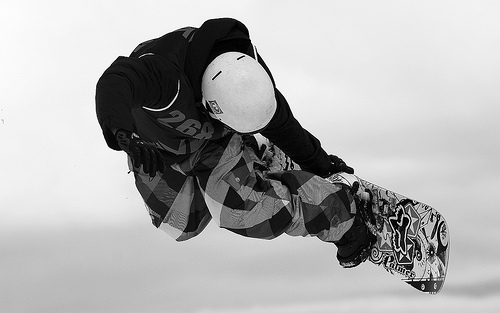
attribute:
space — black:
[209, 70, 223, 80]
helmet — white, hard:
[201, 50, 278, 135]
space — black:
[237, 53, 247, 61]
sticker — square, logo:
[207, 99, 223, 116]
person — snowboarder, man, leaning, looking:
[96, 17, 377, 269]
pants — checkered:
[128, 133, 357, 244]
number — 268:
[157, 108, 214, 143]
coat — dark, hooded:
[96, 17, 333, 174]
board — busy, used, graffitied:
[355, 175, 451, 296]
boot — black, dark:
[337, 181, 376, 269]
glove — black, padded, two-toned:
[116, 130, 169, 177]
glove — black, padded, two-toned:
[328, 152, 357, 176]